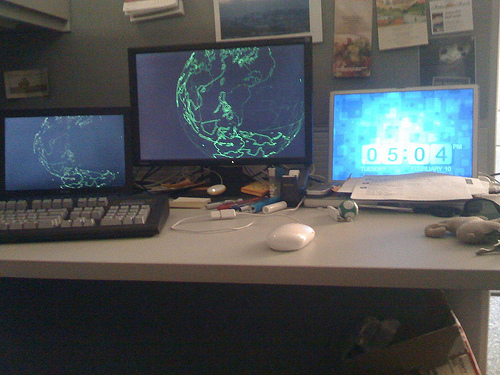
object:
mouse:
[264, 221, 318, 253]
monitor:
[0, 104, 135, 199]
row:
[3, 32, 486, 201]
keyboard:
[0, 184, 171, 244]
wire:
[169, 196, 308, 234]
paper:
[335, 170, 491, 202]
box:
[329, 288, 483, 374]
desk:
[0, 185, 500, 290]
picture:
[211, 0, 324, 46]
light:
[231, 160, 235, 164]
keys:
[133, 214, 146, 224]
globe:
[29, 113, 120, 190]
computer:
[326, 82, 479, 212]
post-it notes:
[240, 179, 269, 198]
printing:
[358, 175, 437, 197]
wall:
[0, 0, 500, 182]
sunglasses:
[410, 196, 500, 221]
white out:
[209, 208, 236, 220]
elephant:
[422, 214, 499, 257]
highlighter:
[260, 199, 288, 214]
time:
[361, 143, 453, 165]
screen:
[330, 88, 474, 181]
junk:
[131, 160, 310, 213]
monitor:
[125, 31, 315, 168]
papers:
[374, 0, 433, 53]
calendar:
[375, 0, 432, 52]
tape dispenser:
[278, 167, 310, 208]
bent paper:
[120, 0, 187, 24]